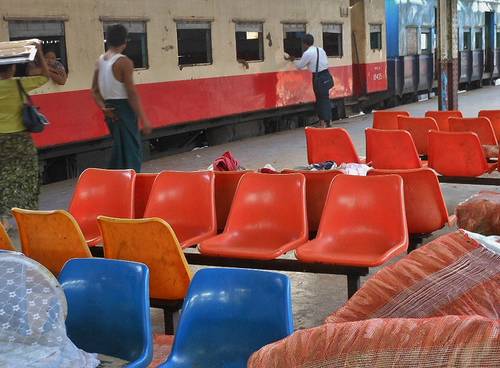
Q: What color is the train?
A: Blue, red and tan.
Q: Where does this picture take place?
A: At a train station.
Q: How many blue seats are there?
A: Three.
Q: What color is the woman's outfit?
A: Green.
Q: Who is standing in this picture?
A: Men and women.